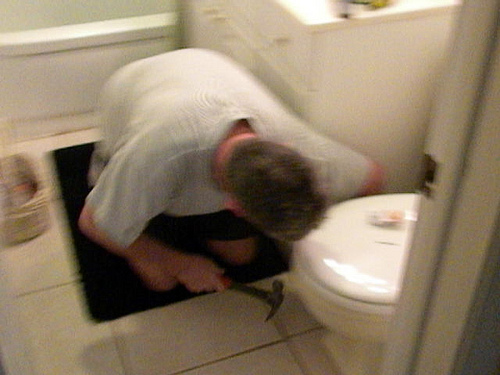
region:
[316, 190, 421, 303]
white plastic toilet lid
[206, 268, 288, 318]
red and black hammer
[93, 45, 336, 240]
grey cotton tee shirt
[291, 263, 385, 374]
white ceramic toilet bowl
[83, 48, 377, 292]
man fixing broken toilet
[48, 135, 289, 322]
black plush bathroom mat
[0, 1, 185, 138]
white ceramic bath tub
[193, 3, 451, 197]
white wood bathroom cabinet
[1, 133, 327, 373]
white tiles on bathroom floor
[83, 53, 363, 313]
man kneeling on bathroom floor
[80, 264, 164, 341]
the mat is black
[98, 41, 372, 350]
the man is bending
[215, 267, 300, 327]
the hammer has red handle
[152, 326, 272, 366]
the tiles are white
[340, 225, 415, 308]
the lid is closed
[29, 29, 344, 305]
the guy is making repairs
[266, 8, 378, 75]
the drwers are closed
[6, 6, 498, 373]
the room is the bathroom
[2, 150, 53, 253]
the basket is on the ground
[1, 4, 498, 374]
the bathroom is dimly lit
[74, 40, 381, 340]
man kneeling on floor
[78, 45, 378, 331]
man holding a hammer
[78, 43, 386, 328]
man kneeling on black rug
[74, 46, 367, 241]
white shirt on man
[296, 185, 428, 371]
white toilet in bathroom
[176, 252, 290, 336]
hand holding hammer with orange handle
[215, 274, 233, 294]
orange handle on hammer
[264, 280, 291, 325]
head of hammer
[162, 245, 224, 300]
right hand of man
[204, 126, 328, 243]
head of man kneeling on floor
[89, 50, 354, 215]
man is bending over next to toilet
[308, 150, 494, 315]
toilet is white with seat down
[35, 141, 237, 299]
man is kneeling on black rug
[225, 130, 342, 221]
man has brown hair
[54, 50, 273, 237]
man is wearing grey shirt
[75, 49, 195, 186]
man is wearing khaki pants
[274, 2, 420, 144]
white lavatory is next to man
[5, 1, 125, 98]
white bathtub is behind man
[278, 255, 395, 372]
body of toilet is off white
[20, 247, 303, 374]
white tiles on bathroom floor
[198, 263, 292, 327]
Person is holding hammer in hand.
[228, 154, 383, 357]
Person is bending over near toilet.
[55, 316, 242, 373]
Large white tiles on bathroom floor.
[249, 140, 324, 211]
Person has dark hair.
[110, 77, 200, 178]
Person wearing t-shirt.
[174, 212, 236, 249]
Person wearing black shorts.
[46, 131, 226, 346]
Black bathmat on floor.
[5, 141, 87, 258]
White basket sitting on floor.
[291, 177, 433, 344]
Toilet is white in color.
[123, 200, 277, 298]
Person is kneeling on ground.